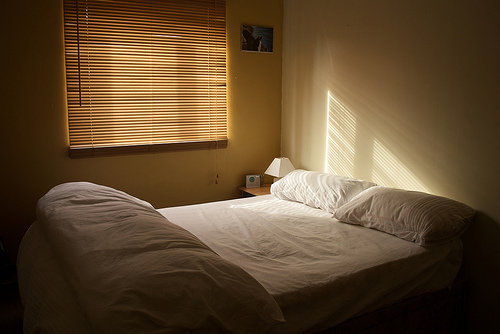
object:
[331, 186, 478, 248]
pillow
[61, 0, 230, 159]
window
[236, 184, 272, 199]
table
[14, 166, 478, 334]
bed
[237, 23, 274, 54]
picture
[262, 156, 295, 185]
lamp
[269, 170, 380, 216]
pillowcases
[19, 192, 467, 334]
sheet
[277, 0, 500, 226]
shadow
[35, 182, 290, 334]
comforter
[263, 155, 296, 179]
lampshade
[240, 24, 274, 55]
picture frame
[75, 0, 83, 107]
control stick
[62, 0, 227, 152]
blinds